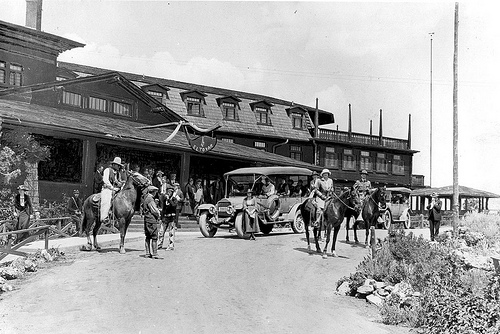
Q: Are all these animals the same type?
A: Yes, all the animals are horses.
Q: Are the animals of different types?
A: No, all the animals are horses.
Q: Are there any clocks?
A: No, there are no clocks.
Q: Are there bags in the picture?
A: No, there are no bags.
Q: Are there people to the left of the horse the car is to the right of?
A: Yes, there are people to the left of the horse.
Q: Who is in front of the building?
A: The people are in front of the building.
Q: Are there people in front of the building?
A: Yes, there are people in front of the building.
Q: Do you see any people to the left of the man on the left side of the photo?
A: Yes, there are people to the left of the man.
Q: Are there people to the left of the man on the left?
A: Yes, there are people to the left of the man.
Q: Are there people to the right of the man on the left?
A: No, the people are to the left of the man.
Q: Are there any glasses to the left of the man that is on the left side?
A: No, there are people to the left of the man.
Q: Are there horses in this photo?
A: Yes, there is a horse.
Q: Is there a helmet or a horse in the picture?
A: Yes, there is a horse.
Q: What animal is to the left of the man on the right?
A: The animal is a horse.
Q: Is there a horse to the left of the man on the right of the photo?
A: Yes, there is a horse to the left of the man.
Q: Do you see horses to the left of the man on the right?
A: Yes, there is a horse to the left of the man.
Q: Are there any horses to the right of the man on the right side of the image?
A: No, the horse is to the left of the man.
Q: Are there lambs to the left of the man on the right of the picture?
A: No, there is a horse to the left of the man.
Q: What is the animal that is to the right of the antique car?
A: The animal is a horse.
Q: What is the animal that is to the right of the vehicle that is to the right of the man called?
A: The animal is a horse.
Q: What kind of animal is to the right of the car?
A: The animal is a horse.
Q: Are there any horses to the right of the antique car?
A: Yes, there is a horse to the right of the car.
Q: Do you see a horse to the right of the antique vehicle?
A: Yes, there is a horse to the right of the car.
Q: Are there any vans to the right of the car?
A: No, there is a horse to the right of the car.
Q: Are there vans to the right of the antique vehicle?
A: No, there is a horse to the right of the car.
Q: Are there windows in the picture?
A: Yes, there are windows.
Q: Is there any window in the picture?
A: Yes, there are windows.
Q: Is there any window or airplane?
A: Yes, there are windows.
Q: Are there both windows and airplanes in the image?
A: Yes, there are both windows and an airplane.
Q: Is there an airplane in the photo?
A: Yes, there is an airplane.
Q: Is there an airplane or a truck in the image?
A: Yes, there is an airplane.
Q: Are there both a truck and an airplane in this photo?
A: No, there is an airplane but no trucks.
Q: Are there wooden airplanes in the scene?
A: Yes, there is a wood airplane.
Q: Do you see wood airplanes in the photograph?
A: Yes, there is a wood airplane.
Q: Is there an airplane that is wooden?
A: Yes, there is an airplane that is wooden.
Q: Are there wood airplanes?
A: Yes, there is an airplane that is made of wood.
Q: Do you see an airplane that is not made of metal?
A: Yes, there is an airplane that is made of wood.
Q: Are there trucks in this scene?
A: No, there are no trucks.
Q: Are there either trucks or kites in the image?
A: No, there are no trucks or kites.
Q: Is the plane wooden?
A: Yes, the plane is wooden.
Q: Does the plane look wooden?
A: Yes, the plane is wooden.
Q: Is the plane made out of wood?
A: Yes, the plane is made of wood.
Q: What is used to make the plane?
A: The plane is made of wood.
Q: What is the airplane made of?
A: The plane is made of wood.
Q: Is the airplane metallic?
A: No, the airplane is wooden.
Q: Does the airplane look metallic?
A: No, the airplane is wooden.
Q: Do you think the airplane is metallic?
A: No, the airplane is wooden.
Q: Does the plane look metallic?
A: No, the plane is wooden.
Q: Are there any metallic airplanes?
A: No, there is an airplane but it is wooden.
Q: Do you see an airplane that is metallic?
A: No, there is an airplane but it is wooden.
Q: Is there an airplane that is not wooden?
A: No, there is an airplane but it is wooden.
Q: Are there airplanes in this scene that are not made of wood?
A: No, there is an airplane but it is made of wood.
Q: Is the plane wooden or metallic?
A: The plane is wooden.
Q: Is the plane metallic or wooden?
A: The plane is wooden.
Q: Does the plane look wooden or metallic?
A: The plane is wooden.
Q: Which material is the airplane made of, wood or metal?
A: The airplane is made of wood.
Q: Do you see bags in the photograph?
A: No, there are no bags.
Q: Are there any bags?
A: No, there are no bags.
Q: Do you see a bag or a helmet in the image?
A: No, there are no bags or helmets.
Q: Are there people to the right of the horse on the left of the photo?
A: Yes, there is a person to the right of the horse.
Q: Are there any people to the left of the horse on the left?
A: No, the person is to the right of the horse.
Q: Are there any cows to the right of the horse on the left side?
A: No, there is a person to the right of the horse.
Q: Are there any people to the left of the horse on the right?
A: Yes, there is a person to the left of the horse.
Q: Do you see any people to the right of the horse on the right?
A: No, the person is to the left of the horse.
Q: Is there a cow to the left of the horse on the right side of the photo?
A: No, there is a person to the left of the horse.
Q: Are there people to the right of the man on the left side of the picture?
A: Yes, there is a person to the right of the man.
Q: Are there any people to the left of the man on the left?
A: No, the person is to the right of the man.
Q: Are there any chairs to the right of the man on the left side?
A: No, there is a person to the right of the man.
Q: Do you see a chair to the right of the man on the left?
A: No, there is a person to the right of the man.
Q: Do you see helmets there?
A: No, there are no helmets.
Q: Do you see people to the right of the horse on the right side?
A: No, the person is to the left of the horse.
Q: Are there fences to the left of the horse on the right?
A: No, there is a person to the left of the horse.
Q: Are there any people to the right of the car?
A: Yes, there is a person to the right of the car.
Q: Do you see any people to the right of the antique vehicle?
A: Yes, there is a person to the right of the car.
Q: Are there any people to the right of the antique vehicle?
A: Yes, there is a person to the right of the car.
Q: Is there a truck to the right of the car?
A: No, there is a person to the right of the car.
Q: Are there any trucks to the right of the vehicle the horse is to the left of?
A: No, there is a person to the right of the car.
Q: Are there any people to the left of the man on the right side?
A: Yes, there is a person to the left of the man.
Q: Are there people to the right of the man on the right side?
A: No, the person is to the left of the man.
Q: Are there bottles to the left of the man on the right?
A: No, there is a person to the left of the man.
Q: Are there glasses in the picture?
A: No, there are no glasses.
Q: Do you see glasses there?
A: No, there are no glasses.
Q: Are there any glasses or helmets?
A: No, there are no glasses or helmets.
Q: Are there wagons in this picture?
A: No, there are no wagons.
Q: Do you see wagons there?
A: No, there are no wagons.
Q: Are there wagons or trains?
A: No, there are no wagons or trains.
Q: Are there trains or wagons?
A: No, there are no wagons or trains.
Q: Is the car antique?
A: Yes, the car is antique.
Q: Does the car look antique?
A: Yes, the car is antique.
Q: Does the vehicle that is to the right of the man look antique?
A: Yes, the car is antique.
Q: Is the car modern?
A: No, the car is antique.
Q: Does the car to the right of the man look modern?
A: No, the car is antique.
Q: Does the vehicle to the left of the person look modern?
A: No, the car is antique.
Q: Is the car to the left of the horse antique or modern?
A: The car is antique.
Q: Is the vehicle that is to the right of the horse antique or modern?
A: The car is antique.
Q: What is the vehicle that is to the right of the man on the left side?
A: The vehicle is a car.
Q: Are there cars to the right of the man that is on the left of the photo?
A: Yes, there is a car to the right of the man.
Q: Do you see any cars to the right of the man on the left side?
A: Yes, there is a car to the right of the man.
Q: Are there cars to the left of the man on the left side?
A: No, the car is to the right of the man.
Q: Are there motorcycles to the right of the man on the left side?
A: No, there is a car to the right of the man.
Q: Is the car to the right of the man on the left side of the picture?
A: Yes, the car is to the right of the man.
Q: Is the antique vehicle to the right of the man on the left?
A: Yes, the car is to the right of the man.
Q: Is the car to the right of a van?
A: No, the car is to the right of the man.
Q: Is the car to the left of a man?
A: No, the car is to the right of a man.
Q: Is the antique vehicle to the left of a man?
A: No, the car is to the right of a man.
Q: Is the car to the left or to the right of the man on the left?
A: The car is to the right of the man.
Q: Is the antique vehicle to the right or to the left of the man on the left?
A: The car is to the right of the man.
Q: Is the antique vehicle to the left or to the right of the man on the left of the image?
A: The car is to the right of the man.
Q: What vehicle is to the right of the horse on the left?
A: The vehicle is a car.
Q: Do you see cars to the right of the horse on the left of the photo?
A: Yes, there is a car to the right of the horse.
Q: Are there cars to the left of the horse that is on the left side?
A: No, the car is to the right of the horse.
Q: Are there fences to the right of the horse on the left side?
A: No, there is a car to the right of the horse.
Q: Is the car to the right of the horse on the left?
A: Yes, the car is to the right of the horse.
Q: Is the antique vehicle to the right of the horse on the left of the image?
A: Yes, the car is to the right of the horse.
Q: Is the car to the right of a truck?
A: No, the car is to the right of the horse.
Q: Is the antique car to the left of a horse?
A: No, the car is to the right of a horse.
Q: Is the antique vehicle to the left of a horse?
A: No, the car is to the right of a horse.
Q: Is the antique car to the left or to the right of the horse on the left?
A: The car is to the right of the horse.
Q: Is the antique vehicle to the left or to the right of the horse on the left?
A: The car is to the right of the horse.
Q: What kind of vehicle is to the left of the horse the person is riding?
A: The vehicle is a car.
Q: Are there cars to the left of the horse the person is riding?
A: Yes, there is a car to the left of the horse.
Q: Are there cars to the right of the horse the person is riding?
A: No, the car is to the left of the horse.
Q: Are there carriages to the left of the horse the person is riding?
A: No, there is a car to the left of the horse.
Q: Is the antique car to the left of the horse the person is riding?
A: Yes, the car is to the left of the horse.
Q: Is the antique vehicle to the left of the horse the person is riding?
A: Yes, the car is to the left of the horse.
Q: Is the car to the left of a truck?
A: No, the car is to the left of the horse.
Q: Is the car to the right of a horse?
A: No, the car is to the left of a horse.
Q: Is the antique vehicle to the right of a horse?
A: No, the car is to the left of a horse.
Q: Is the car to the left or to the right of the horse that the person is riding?
A: The car is to the left of the horse.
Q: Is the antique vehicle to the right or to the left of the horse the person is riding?
A: The car is to the left of the horse.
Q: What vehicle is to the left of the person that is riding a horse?
A: The vehicle is a car.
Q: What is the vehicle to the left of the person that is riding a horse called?
A: The vehicle is a car.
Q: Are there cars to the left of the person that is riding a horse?
A: Yes, there is a car to the left of the person.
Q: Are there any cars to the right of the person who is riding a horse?
A: No, the car is to the left of the person.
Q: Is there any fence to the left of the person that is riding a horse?
A: No, there is a car to the left of the person.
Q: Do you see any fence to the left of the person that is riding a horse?
A: No, there is a car to the left of the person.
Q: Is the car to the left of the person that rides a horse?
A: Yes, the car is to the left of the person.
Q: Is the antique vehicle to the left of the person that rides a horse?
A: Yes, the car is to the left of the person.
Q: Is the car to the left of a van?
A: No, the car is to the left of the person.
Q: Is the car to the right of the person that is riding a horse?
A: No, the car is to the left of the person.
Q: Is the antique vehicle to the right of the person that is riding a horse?
A: No, the car is to the left of the person.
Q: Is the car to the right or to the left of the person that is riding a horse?
A: The car is to the left of the person.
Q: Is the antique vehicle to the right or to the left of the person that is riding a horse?
A: The car is to the left of the person.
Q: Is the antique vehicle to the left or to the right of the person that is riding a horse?
A: The car is to the left of the person.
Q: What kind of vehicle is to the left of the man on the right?
A: The vehicle is a car.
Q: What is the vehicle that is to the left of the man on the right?
A: The vehicle is a car.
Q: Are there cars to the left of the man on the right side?
A: Yes, there is a car to the left of the man.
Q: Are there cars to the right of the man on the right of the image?
A: No, the car is to the left of the man.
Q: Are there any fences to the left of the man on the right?
A: No, there is a car to the left of the man.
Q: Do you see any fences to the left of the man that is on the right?
A: No, there is a car to the left of the man.